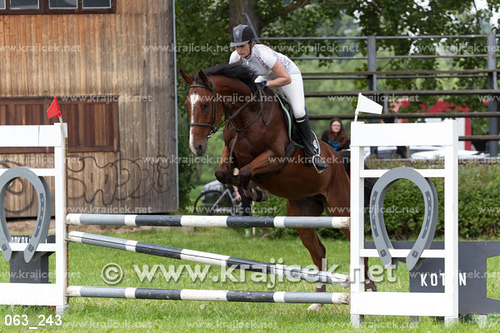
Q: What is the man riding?
A: Horse.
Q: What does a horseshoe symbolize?
A: Good luck.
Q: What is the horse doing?
A: Jumping.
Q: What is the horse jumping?
A: Fence.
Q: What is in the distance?
A: Stands.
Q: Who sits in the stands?
A: Spectators.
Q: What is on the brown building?
A: Graffiti.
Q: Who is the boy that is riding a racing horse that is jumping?
A: Boy in blue cap.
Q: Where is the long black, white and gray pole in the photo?
A: Near the ground.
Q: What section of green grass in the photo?
A: Grass where horse is jumping.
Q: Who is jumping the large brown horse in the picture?
A: Boy in white.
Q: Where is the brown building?
A: Far left.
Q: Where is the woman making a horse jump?
A: Over the pole.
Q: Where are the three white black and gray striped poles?
A: Center of photo.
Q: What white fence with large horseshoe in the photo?
A: Right and left of photo.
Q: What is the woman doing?
A: Riding a horse.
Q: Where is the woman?
A: On a brown horse.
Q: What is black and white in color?
A: Poles.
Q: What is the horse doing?
A: Jumping over barrier.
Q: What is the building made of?
A: Wood.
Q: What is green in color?
A: The grass.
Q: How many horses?
A: One.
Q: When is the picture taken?
A: Daytime.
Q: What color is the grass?
A: Green.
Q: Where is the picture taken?
A: At a horse jumping competition.